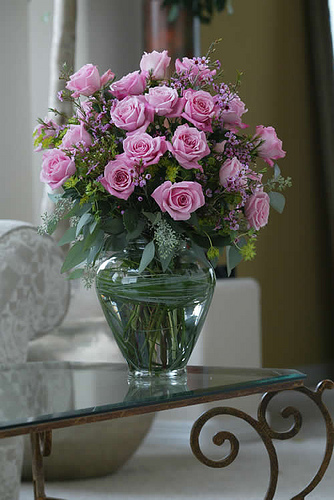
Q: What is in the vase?
A: Pink roses.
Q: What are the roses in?
A: Vase.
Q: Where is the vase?
A: On glass table.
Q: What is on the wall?
A: Yellow paint.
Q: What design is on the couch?
A: Floral design.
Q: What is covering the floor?
A: White carpet.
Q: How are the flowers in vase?
A: Purple.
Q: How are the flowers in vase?
A: Bunch.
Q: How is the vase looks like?
A: Wide and round.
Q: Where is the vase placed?
A: Table.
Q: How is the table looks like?
A: Clear.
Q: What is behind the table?
A: Sofa.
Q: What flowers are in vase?
A: Lavender.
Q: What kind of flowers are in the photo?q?
A: Roses.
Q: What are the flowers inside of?
A: Vase.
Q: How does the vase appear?
A: Clear.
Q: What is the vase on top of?
A: Table.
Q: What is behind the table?
A: Sofa.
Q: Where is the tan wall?
A: Behind sofa.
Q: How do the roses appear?
A: Fresh.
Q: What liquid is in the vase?
A: Water.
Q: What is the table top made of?
A: Glass.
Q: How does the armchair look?
A: Has a gray and white pattern.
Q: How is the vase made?
A: The vase is clear glass.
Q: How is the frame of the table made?
A: Frame has wrought iron curly Q's.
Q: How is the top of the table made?
A: Large glass top.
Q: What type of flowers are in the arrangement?
A: Roses and baby's breath flowers.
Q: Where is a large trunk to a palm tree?
A: To the left behind roses.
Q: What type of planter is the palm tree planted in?
A: Ceramic planter.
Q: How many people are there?
A: Zero.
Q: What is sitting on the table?
A: A vase of flowers.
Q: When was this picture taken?
A: During the daytime.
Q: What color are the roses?
A: Pink.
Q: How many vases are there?
A: One.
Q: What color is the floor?
A: White.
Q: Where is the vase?
A: On a glass tabletop.